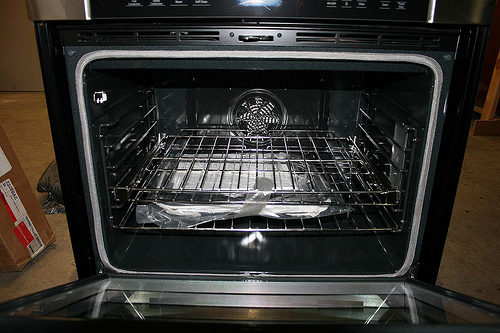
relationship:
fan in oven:
[236, 96, 279, 138] [0, 1, 498, 331]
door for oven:
[0, 272, 499, 332] [0, 1, 498, 331]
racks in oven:
[110, 128, 399, 233] [0, 1, 498, 331]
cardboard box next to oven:
[0, 125, 56, 273] [0, 1, 498, 331]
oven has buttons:
[0, 1, 498, 331] [124, 0, 408, 8]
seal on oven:
[75, 50, 442, 277] [0, 1, 498, 331]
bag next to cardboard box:
[36, 159, 67, 214] [0, 125, 56, 273]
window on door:
[41, 290, 475, 325] [0, 272, 499, 332]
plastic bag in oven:
[134, 154, 355, 229] [0, 1, 498, 331]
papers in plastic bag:
[173, 153, 298, 193] [134, 154, 355, 229]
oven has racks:
[0, 1, 498, 331] [110, 128, 399, 233]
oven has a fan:
[0, 1, 498, 331] [236, 96, 279, 138]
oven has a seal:
[0, 1, 498, 331] [75, 50, 442, 277]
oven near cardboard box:
[0, 1, 498, 331] [0, 125, 56, 273]